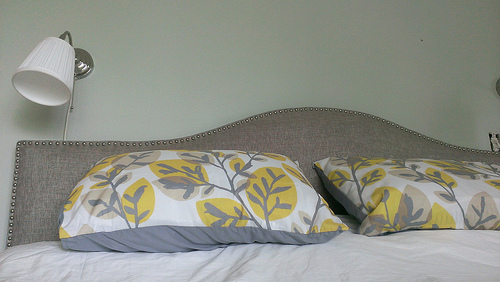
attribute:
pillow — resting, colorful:
[59, 149, 350, 253]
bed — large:
[0, 108, 498, 281]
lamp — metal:
[11, 31, 94, 140]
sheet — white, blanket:
[0, 213, 499, 281]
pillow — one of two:
[312, 155, 499, 236]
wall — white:
[1, 0, 500, 251]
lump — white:
[189, 244, 266, 281]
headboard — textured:
[5, 107, 498, 241]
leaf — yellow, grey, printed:
[120, 177, 155, 224]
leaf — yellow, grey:
[360, 167, 386, 187]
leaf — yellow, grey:
[247, 166, 298, 220]